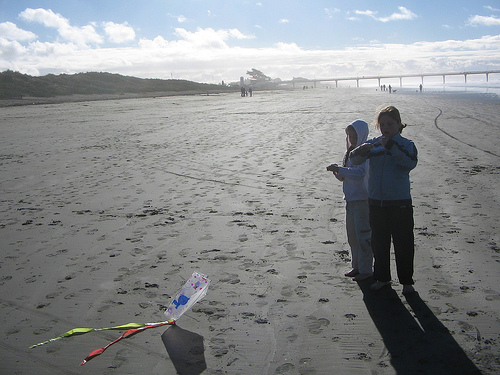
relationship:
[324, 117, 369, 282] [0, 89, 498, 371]
child on beach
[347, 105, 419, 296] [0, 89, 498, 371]
barefoot girls on beach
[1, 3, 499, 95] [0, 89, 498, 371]
sky above beach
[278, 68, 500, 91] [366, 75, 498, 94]
bridge above water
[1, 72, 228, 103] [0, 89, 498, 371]
hill beside beach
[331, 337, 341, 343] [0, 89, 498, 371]
foot prints on beach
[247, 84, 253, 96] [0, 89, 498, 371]
person on beach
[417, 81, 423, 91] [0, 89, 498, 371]
person on beach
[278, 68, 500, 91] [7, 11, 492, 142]
bridge in background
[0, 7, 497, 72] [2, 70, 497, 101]
clouds on horizon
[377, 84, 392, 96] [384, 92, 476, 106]
friends on beach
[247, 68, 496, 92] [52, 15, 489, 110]
bridge in background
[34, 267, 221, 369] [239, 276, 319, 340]
kite lying in sand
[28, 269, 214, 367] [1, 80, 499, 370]
kite on ground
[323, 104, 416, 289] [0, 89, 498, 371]
barefoot girls on beach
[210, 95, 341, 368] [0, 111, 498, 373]
foot prints on sand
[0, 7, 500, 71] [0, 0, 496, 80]
clouds in sky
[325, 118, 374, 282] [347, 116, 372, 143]
child with hood